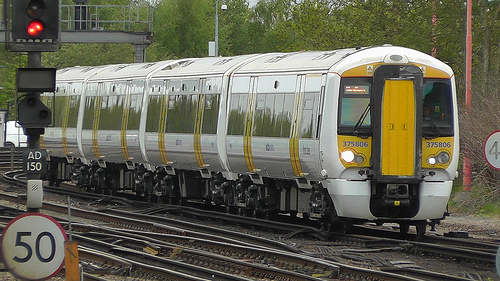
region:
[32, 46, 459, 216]
white and yellow train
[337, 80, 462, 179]
yellow front of train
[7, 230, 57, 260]
black numbers on white background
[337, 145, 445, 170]
front lights on train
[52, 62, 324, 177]
side of yellow and white train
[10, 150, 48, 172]
white lettering on black background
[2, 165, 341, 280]
unused tracks by train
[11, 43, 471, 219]
train traveling down tracks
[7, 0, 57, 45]
black traffic signal withe red light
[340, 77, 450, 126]
front windows of train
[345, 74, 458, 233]
front of passenger train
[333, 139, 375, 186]
headlamps of yellow train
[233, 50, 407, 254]
train is yellow and white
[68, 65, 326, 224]
train has 3 cars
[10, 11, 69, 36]
red light on signal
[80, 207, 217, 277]
many train tracks on ground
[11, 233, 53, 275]
red and white sign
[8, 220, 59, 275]
sign says number 50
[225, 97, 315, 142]
windows of yellow train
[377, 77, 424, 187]
yellow door of train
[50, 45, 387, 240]
This is a train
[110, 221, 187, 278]
This is a picture of tracks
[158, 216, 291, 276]
The tracks are made of steel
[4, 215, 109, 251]
This number says 50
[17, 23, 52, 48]
This is a picture of a stop sign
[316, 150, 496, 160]
These lights are white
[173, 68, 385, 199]
The train is white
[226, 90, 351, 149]
These are windows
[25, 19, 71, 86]
The light is red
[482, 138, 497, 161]
The sign says "4"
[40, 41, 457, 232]
a white train on the tracks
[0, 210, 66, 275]
the round sign under the red light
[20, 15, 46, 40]
the red light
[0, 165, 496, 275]
the train tracks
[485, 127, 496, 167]
a round sign in front of the train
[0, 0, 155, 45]
a gray platform above the train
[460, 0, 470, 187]
a tall pole closest to the train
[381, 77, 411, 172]
a yellow rectangle on front of the train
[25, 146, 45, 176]
small square sign under the red light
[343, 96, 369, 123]
the train's left windshield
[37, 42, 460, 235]
a yellow and white train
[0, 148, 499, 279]
a yellow and white train on the track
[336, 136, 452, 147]
numbers on both side of train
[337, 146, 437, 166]
two bright front lights on train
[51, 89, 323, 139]
a line of windows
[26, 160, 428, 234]
a line of black metal wheels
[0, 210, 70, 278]
a round red and white sign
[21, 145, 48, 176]
black sign with AD up top and 150 below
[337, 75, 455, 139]
windshield on both sides of train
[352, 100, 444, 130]
two windshield wipers on train